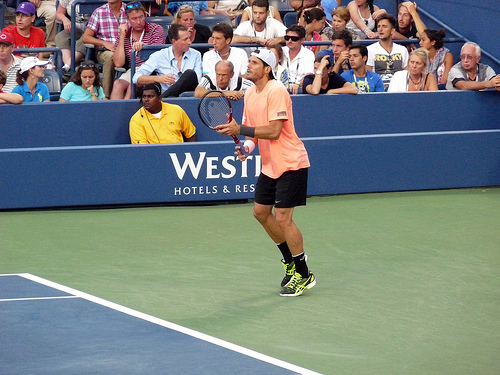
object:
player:
[196, 48, 315, 297]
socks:
[292, 251, 309, 278]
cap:
[250, 49, 278, 80]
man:
[364, 13, 410, 85]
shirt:
[341, 69, 386, 92]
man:
[127, 82, 197, 146]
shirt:
[128, 101, 196, 145]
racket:
[197, 90, 251, 158]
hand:
[214, 114, 241, 135]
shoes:
[279, 270, 317, 297]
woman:
[386, 47, 438, 92]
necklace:
[409, 72, 423, 86]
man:
[0, 31, 24, 94]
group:
[0, 1, 499, 105]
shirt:
[240, 79, 310, 180]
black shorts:
[254, 168, 309, 208]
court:
[0, 271, 325, 375]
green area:
[0, 194, 499, 375]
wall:
[0, 89, 500, 211]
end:
[19, 271, 320, 375]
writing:
[168, 151, 207, 180]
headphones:
[142, 84, 161, 95]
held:
[212, 113, 250, 164]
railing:
[416, 7, 500, 72]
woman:
[58, 59, 106, 103]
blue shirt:
[59, 81, 106, 101]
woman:
[11, 56, 50, 104]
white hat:
[19, 56, 53, 75]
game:
[0, 0, 484, 375]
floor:
[0, 188, 500, 375]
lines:
[0, 295, 80, 302]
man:
[0, 2, 45, 60]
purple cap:
[14, 1, 38, 17]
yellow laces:
[288, 276, 302, 289]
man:
[446, 41, 500, 91]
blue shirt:
[11, 80, 51, 104]